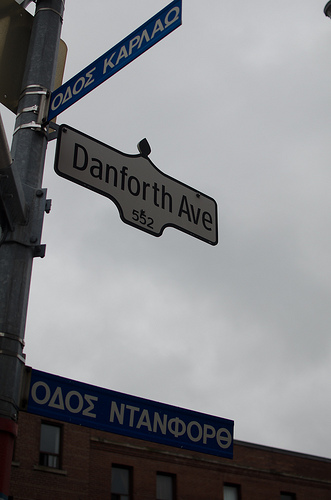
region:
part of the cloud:
[278, 402, 292, 418]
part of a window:
[167, 480, 172, 486]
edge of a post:
[120, 428, 141, 445]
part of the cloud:
[247, 380, 257, 394]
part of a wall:
[230, 461, 237, 470]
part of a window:
[222, 487, 224, 490]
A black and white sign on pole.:
[71, 139, 221, 238]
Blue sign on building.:
[34, 377, 228, 455]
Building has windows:
[97, 465, 214, 494]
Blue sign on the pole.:
[53, 54, 157, 79]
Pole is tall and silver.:
[35, 68, 45, 293]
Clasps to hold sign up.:
[22, 83, 50, 132]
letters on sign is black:
[80, 153, 199, 214]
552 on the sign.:
[123, 204, 154, 225]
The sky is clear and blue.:
[173, 62, 301, 140]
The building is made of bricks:
[19, 447, 96, 498]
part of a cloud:
[301, 396, 312, 410]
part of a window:
[166, 484, 171, 489]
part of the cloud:
[258, 388, 274, 411]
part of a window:
[160, 484, 172, 497]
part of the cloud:
[178, 374, 188, 393]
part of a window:
[133, 475, 140, 483]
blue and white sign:
[48, 11, 194, 116]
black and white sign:
[60, 115, 220, 249]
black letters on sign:
[64, 136, 217, 246]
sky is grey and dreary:
[153, 52, 327, 176]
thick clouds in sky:
[193, 53, 313, 183]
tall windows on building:
[38, 418, 224, 497]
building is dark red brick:
[19, 424, 296, 490]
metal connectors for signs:
[23, 77, 57, 148]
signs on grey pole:
[28, 23, 69, 323]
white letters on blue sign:
[37, 3, 184, 120]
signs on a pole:
[7, 1, 241, 258]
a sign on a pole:
[0, 333, 249, 465]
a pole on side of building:
[0, 1, 67, 430]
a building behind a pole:
[8, 397, 327, 498]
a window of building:
[29, 414, 72, 478]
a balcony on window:
[32, 412, 66, 476]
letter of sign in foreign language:
[19, 360, 242, 464]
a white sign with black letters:
[55, 120, 226, 255]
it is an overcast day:
[18, 5, 328, 498]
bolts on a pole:
[28, 178, 62, 265]